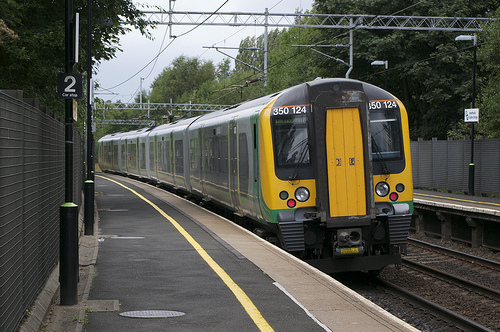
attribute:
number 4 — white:
[300, 106, 307, 114]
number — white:
[296, 105, 302, 115]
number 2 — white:
[384, 99, 394, 112]